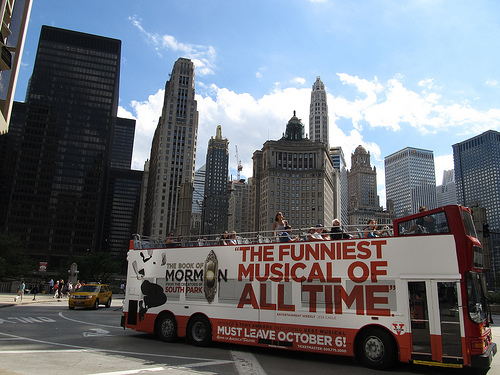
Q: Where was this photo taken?
A: New York City.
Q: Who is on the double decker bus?
A: Tourists.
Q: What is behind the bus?
A: Buildings.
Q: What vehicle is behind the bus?
A: Taxi.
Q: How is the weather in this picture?
A: Partly cloudy.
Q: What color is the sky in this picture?
A: Blue.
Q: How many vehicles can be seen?
A: Two.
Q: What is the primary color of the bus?
A: Red.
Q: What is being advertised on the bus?
A: A musical.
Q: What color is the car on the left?
A: Yellow.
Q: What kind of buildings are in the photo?
A: Skyscrapers.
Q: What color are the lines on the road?
A: White.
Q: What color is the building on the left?
A: Black.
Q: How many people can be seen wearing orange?
A: Zero.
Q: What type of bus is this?
A: Double decker.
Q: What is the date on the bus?
A: October 6.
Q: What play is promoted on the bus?
A: The Book of Mormon.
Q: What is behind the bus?
A: A yellow SUV.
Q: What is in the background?
A: Tall buildings.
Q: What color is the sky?
A: Blue.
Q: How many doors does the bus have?
A: Two.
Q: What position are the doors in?
A: Closed.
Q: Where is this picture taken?
A: A city.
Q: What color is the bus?
A: White and red.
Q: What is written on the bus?
A: The funniest musical of all time.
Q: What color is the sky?
A: Blue.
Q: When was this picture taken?
A: Daytime.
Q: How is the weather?
A: Clear.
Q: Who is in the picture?
A: Tourists.